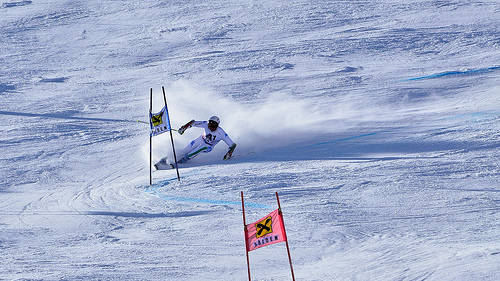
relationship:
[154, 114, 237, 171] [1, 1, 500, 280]
person in snow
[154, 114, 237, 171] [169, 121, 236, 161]
person wearing snow gear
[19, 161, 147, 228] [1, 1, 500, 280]
tracks are in snow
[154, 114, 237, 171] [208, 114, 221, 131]
person has head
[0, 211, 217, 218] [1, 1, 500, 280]
shadow on snow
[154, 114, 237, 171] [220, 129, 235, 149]
person has arm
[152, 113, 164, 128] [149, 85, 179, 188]
icon on sign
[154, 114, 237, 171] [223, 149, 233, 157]
person has hand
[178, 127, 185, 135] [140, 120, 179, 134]
hand holding ski pole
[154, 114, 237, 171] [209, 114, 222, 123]
person wearing helmet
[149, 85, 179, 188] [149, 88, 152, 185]
sign attached to stick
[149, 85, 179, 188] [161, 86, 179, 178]
sign attached to stick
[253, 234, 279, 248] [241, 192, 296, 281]
letters are on sign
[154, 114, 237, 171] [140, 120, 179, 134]
person holding ski pole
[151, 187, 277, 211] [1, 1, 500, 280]
line in snow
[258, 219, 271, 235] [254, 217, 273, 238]
x on icon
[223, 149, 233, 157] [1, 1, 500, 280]
hand in snow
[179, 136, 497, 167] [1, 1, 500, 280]
shadow in snow